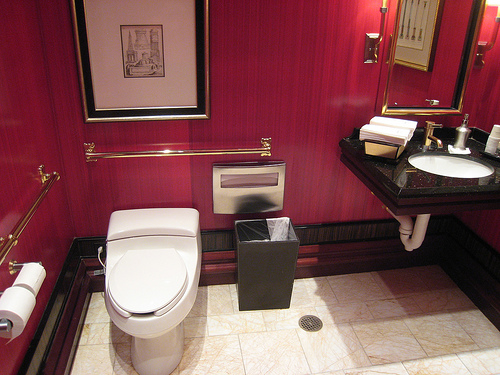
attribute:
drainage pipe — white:
[381, 202, 433, 251]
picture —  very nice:
[69, 4, 206, 126]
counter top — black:
[343, 122, 498, 205]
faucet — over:
[401, 107, 482, 169]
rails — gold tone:
[81, 135, 276, 160]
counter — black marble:
[337, 124, 499, 218]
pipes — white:
[376, 214, 430, 247]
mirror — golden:
[374, 1, 485, 119]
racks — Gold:
[113, 144, 210, 165]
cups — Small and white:
[461, 114, 498, 159]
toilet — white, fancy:
[102, 224, 202, 373]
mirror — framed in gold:
[381, 10, 491, 124]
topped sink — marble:
[403, 131, 471, 188]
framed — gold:
[192, 53, 222, 191]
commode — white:
[118, 172, 179, 366]